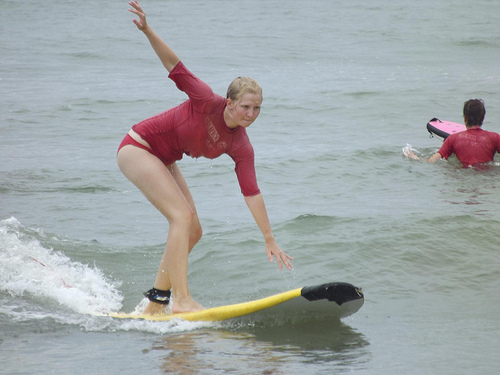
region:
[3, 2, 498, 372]
two surfers in the water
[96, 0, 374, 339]
female surfer in the water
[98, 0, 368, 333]
girl in red shirt surfing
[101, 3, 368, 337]
girl in red shirt balancing on surfboard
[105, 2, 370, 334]
surfer riding the waves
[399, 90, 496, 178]
surfer in the water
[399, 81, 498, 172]
surfer wearing red in the water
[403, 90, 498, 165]
surfer with pink surfboard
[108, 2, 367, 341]
surfer on yellow surfboard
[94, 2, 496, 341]
two surfers wearing red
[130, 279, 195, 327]
The strap on the surfers leg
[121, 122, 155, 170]
The bottom of the surfers bathing suit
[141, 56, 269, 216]
The top of the surfers bathing suit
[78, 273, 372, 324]
Yellow,black and white surfboard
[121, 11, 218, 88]
The ladies arm raised in the air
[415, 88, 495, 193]
The surfer in the background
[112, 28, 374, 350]
A surfer riding a yellow black and white surfboard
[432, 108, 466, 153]
The pin surfboard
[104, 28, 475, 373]
Two people in the ocean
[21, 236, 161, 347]
The foam of the wave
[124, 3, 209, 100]
woman's arm extended upwards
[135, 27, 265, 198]
woman's shirt is red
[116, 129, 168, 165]
woman wearing a bikini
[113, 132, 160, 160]
the bikini is red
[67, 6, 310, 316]
woman leaning forward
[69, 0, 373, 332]
woman standing on surfboard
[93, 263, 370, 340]
surfboard is yellow and black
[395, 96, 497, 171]
man standing in water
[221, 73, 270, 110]
woman's hair is wet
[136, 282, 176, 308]
black band around woman's ankle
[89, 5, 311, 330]
this is a woman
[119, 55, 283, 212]
woman wearing red shirt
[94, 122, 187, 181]
woman wearing red bottom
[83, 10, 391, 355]
woman on a surfboard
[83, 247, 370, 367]
a yellow and white surfboard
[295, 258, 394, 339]
black tip on surfboard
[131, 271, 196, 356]
black ankle tie on woman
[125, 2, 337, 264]
woman has arms extended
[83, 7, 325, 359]
a bent over woman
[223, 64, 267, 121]
woman with blonde hair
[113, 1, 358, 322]
a person standing on a surf board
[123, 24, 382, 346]
a surfer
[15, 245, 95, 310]
splashes from the surf board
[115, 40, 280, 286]
a lady wearing a red shirt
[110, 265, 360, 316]
a yellow surf board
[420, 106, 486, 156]
a person in the water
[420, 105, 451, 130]
a pink surf board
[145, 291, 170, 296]
the ankle bracelet on the surf board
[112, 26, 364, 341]
a lady in the water